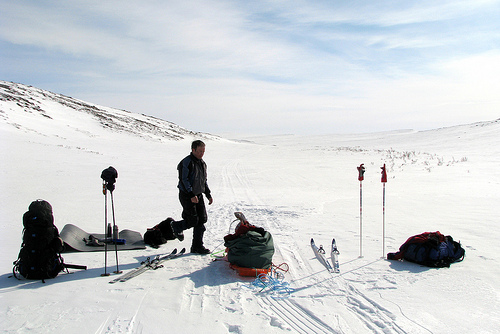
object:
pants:
[146, 195, 208, 255]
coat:
[174, 157, 212, 194]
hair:
[191, 140, 203, 156]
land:
[1, 77, 226, 142]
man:
[149, 137, 216, 255]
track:
[223, 190, 416, 334]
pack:
[12, 198, 88, 284]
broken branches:
[241, 168, 265, 192]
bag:
[387, 229, 469, 270]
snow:
[0, 69, 497, 334]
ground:
[0, 139, 500, 333]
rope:
[249, 270, 299, 297]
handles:
[356, 166, 365, 182]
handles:
[102, 179, 107, 195]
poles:
[104, 197, 109, 273]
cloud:
[1, 0, 500, 139]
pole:
[375, 161, 392, 256]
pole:
[358, 160, 368, 260]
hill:
[0, 84, 499, 333]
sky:
[0, 0, 500, 142]